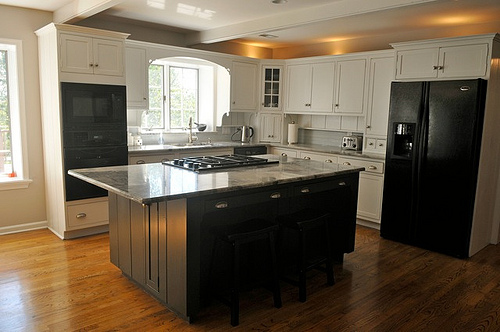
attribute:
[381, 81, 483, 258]
refrigerator — black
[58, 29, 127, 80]
cabinet — white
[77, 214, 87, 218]
handle — silver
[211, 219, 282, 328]
stool — black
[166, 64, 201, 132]
window — closed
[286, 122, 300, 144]
paper towels — white, roll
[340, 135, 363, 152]
toaster — gray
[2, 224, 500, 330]
floor — brown, pictured, wood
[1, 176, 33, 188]
windowsill — white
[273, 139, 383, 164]
counter — grey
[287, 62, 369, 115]
cabinets — white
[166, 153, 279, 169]
stove burner — black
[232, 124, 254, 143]
coffee maker — stainless steel